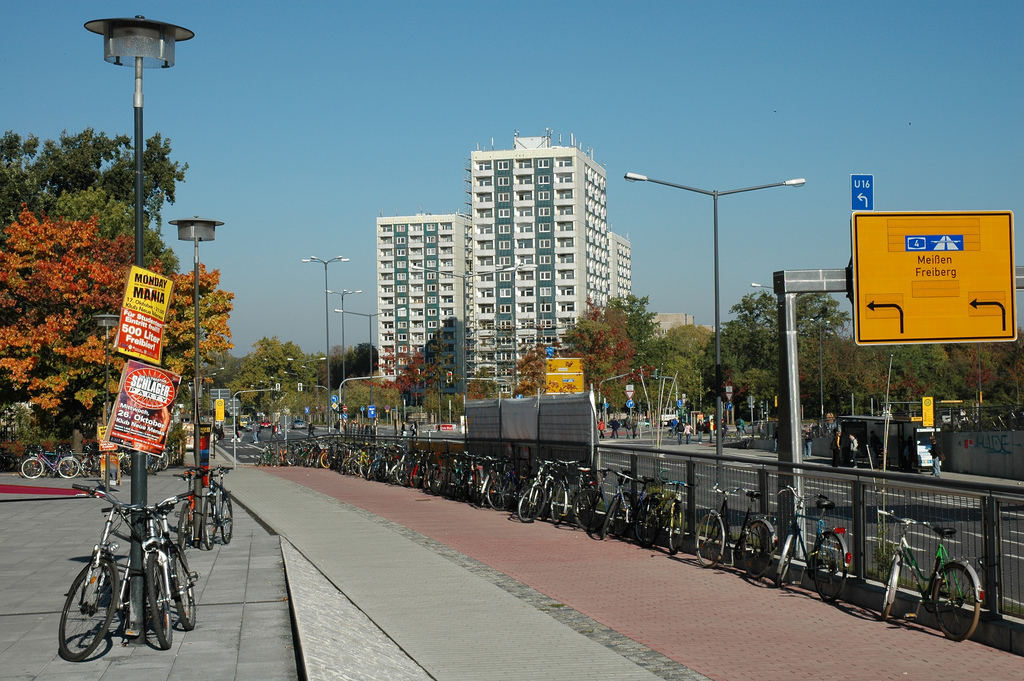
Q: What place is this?
A: It is a street.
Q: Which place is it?
A: It is a street.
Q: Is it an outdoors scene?
A: Yes, it is outdoors.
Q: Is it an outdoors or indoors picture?
A: It is outdoors.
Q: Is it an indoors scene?
A: No, it is outdoors.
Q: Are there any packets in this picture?
A: No, there are no packets.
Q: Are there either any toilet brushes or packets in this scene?
A: No, there are no packets or toilet brushes.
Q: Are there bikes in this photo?
A: Yes, there are bikes.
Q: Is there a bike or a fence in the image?
A: Yes, there are bikes.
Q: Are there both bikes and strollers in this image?
A: No, there are bikes but no strollers.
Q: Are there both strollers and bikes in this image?
A: No, there are bikes but no strollers.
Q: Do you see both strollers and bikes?
A: No, there are bikes but no strollers.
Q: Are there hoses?
A: No, there are no hoses.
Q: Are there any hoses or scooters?
A: No, there are no hoses or scooters.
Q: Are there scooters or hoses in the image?
A: No, there are no hoses or scooters.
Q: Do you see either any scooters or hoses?
A: No, there are no hoses or scooters.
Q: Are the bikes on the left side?
A: Yes, the bikes are on the left of the image.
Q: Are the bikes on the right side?
A: No, the bikes are on the left of the image.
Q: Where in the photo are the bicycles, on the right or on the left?
A: The bicycles are on the left of the image.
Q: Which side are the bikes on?
A: The bikes are on the left of the image.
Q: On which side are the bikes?
A: The bikes are on the left of the image.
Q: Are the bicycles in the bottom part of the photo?
A: Yes, the bicycles are in the bottom of the image.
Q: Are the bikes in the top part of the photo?
A: No, the bikes are in the bottom of the image.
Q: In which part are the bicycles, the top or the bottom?
A: The bicycles are in the bottom of the image.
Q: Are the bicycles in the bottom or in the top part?
A: The bicycles are in the bottom of the image.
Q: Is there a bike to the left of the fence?
A: Yes, there are bikes to the left of the fence.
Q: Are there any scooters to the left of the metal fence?
A: No, there are bikes to the left of the fence.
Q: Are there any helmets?
A: No, there are no helmets.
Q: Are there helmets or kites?
A: No, there are no helmets or kites.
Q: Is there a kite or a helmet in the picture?
A: No, there are no helmets or kites.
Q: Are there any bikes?
A: Yes, there is a bike.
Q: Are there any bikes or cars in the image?
A: Yes, there is a bike.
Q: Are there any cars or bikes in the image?
A: Yes, there is a bike.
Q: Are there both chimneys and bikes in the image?
A: No, there is a bike but no chimneys.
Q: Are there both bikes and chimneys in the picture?
A: No, there is a bike but no chimneys.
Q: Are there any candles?
A: No, there are no candles.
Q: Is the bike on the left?
A: Yes, the bike is on the left of the image.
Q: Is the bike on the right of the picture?
A: No, the bike is on the left of the image.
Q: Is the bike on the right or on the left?
A: The bike is on the left of the image.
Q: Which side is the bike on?
A: The bike is on the left of the image.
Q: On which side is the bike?
A: The bike is on the left of the image.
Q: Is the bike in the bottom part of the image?
A: Yes, the bike is in the bottom of the image.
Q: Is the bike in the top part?
A: No, the bike is in the bottom of the image.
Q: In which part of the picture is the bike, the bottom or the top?
A: The bike is in the bottom of the image.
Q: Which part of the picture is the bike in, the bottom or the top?
A: The bike is in the bottom of the image.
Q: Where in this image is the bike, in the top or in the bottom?
A: The bike is in the bottom of the image.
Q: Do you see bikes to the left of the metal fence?
A: Yes, there is a bike to the left of the fence.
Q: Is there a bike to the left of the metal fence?
A: Yes, there is a bike to the left of the fence.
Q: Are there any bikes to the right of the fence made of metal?
A: No, the bike is to the left of the fence.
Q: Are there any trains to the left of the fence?
A: No, there is a bike to the left of the fence.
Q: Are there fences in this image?
A: Yes, there is a fence.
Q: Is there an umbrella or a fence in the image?
A: Yes, there is a fence.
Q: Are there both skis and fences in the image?
A: No, there is a fence but no skis.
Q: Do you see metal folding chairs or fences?
A: Yes, there is a metal fence.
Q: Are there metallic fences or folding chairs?
A: Yes, there is a metal fence.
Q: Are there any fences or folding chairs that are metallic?
A: Yes, the fence is metallic.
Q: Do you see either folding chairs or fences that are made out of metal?
A: Yes, the fence is made of metal.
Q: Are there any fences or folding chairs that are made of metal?
A: Yes, the fence is made of metal.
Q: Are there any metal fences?
A: Yes, there is a metal fence.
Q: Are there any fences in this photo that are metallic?
A: Yes, there is a fence that is metallic.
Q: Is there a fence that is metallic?
A: Yes, there is a fence that is metallic.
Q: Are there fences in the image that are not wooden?
A: Yes, there is a metallic fence.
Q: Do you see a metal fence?
A: Yes, there is a fence that is made of metal.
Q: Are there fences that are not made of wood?
A: Yes, there is a fence that is made of metal.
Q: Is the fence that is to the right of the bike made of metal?
A: Yes, the fence is made of metal.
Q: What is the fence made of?
A: The fence is made of metal.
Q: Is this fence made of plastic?
A: No, the fence is made of metal.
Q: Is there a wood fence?
A: No, there is a fence but it is made of metal.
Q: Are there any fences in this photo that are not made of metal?
A: No, there is a fence but it is made of metal.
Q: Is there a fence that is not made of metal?
A: No, there is a fence but it is made of metal.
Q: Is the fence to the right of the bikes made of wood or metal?
A: The fence is made of metal.